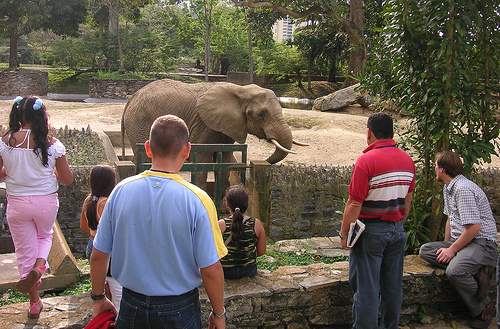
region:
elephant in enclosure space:
[113, 81, 306, 204]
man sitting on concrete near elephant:
[433, 147, 499, 301]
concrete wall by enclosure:
[238, 261, 489, 323]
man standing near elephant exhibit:
[76, 112, 237, 322]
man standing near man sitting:
[349, 98, 418, 327]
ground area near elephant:
[312, 111, 367, 155]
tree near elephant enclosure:
[353, 5, 493, 237]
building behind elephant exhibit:
[266, 18, 310, 44]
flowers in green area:
[289, 248, 313, 250]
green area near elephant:
[256, 240, 337, 266]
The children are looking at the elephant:
[17, 80, 281, 321]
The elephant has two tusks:
[262, 113, 310, 165]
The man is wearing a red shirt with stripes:
[344, 138, 419, 228]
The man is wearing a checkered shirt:
[437, 163, 497, 242]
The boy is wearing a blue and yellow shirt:
[94, 154, 228, 299]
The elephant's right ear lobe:
[195, 72, 253, 151]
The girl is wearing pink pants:
[3, 187, 59, 274]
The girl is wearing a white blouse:
[6, 131, 68, 192]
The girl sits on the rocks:
[217, 213, 269, 315]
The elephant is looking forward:
[125, 76, 310, 198]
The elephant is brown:
[123, 79, 310, 184]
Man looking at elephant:
[90, 115, 227, 327]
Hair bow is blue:
[33, 99, 40, 109]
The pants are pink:
[5, 197, 57, 279]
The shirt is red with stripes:
[348, 139, 414, 223]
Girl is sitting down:
[217, 187, 268, 279]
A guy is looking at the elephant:
[419, 151, 495, 321]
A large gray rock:
[311, 82, 360, 111]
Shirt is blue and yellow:
[92, 169, 227, 293]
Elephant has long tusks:
[274, 139, 308, 154]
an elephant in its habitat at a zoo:
[117, 70, 309, 212]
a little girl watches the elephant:
[212, 178, 272, 279]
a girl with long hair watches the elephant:
[75, 160, 120, 265]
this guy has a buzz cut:
[86, 110, 231, 321]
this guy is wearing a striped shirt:
[336, 106, 416, 322]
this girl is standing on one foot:
[0, 90, 75, 320]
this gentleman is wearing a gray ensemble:
[416, 145, 498, 327]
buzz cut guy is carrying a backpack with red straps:
[79, 303, 119, 327]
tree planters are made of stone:
[1, 63, 51, 98]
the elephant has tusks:
[266, 133, 312, 157]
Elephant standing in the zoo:
[161, 68, 272, 109]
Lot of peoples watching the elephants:
[11, 102, 463, 279]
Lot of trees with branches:
[33, 14, 416, 54]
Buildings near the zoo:
[276, 20, 292, 37]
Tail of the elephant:
[118, 122, 127, 160]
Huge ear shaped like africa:
[200, 83, 243, 140]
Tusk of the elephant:
[274, 135, 314, 153]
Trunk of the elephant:
[268, 152, 294, 170]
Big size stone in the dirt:
[298, 83, 363, 115]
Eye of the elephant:
[253, 105, 273, 119]